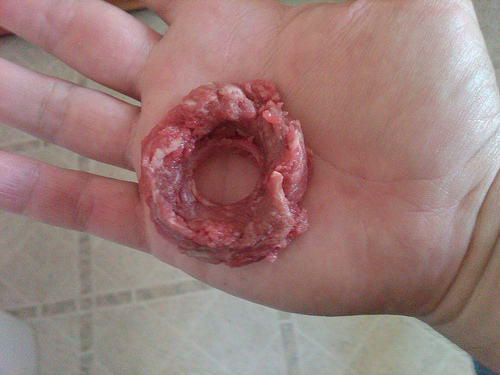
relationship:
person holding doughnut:
[6, 4, 496, 373] [137, 80, 315, 269]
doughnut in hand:
[137, 80, 315, 269] [6, 4, 496, 373]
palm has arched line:
[305, 12, 480, 287] [316, 145, 438, 195]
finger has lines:
[0, 66, 143, 160] [24, 76, 84, 146]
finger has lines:
[2, 156, 152, 254] [17, 159, 49, 216]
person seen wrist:
[6, 4, 496, 373] [435, 171, 499, 358]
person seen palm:
[6, 4, 496, 373] [305, 12, 480, 287]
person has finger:
[6, 4, 496, 373] [0, 66, 143, 160]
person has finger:
[6, 4, 496, 373] [2, 156, 152, 254]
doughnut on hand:
[137, 80, 315, 269] [6, 4, 496, 373]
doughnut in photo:
[137, 80, 315, 269] [6, 4, 496, 373]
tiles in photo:
[1, 265, 184, 375] [6, 4, 496, 373]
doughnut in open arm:
[137, 80, 315, 269] [6, 4, 496, 373]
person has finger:
[6, 4, 496, 373] [4, 1, 160, 80]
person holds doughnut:
[6, 4, 496, 373] [137, 80, 315, 269]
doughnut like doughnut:
[137, 80, 315, 269] [126, 71, 318, 274]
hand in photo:
[6, 4, 496, 373] [6, 4, 496, 373]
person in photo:
[6, 4, 496, 373] [6, 4, 496, 373]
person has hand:
[6, 4, 496, 373] [6, 4, 496, 373]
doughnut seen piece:
[137, 80, 315, 269] [235, 200, 280, 243]